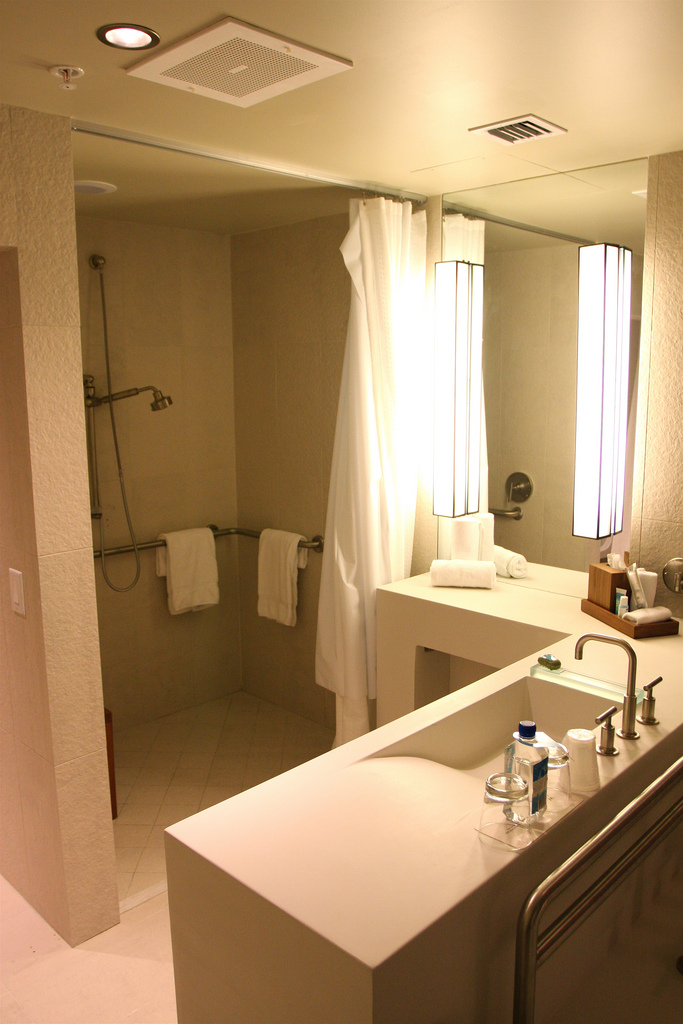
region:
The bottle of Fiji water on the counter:
[502, 711, 556, 831]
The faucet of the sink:
[569, 630, 646, 745]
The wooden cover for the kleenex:
[585, 544, 638, 608]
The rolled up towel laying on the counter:
[419, 550, 510, 595]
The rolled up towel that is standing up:
[446, 507, 477, 577]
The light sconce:
[426, 245, 487, 539]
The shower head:
[79, 242, 178, 619]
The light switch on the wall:
[5, 570, 35, 634]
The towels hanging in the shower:
[143, 514, 318, 629]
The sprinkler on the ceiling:
[32, 50, 92, 100]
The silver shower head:
[151, 388, 177, 416]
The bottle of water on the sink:
[491, 709, 558, 832]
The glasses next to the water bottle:
[477, 739, 573, 848]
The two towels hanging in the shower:
[155, 526, 314, 631]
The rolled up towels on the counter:
[427, 507, 530, 601]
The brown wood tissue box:
[584, 557, 641, 611]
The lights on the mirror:
[430, 241, 640, 540]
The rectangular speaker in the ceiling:
[119, 12, 354, 111]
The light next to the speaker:
[93, 18, 163, 52]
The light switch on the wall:
[3, 564, 31, 622]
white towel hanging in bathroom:
[140, 521, 244, 624]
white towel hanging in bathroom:
[250, 522, 311, 627]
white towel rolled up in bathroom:
[431, 537, 508, 592]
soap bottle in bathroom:
[492, 734, 555, 831]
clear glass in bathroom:
[485, 772, 527, 861]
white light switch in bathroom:
[1, 556, 36, 622]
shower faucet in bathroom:
[112, 380, 198, 414]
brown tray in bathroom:
[580, 563, 663, 631]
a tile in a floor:
[225, 682, 256, 713]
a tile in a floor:
[262, 702, 278, 725]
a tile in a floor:
[276, 705, 316, 736]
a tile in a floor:
[284, 748, 302, 772]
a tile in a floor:
[243, 740, 283, 771]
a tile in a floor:
[216, 730, 248, 756]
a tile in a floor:
[178, 717, 212, 752]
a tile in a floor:
[143, 718, 181, 748]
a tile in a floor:
[158, 778, 196, 804]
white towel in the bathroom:
[156, 524, 228, 614]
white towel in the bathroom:
[247, 524, 300, 627]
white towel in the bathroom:
[420, 549, 484, 586]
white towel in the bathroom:
[486, 539, 524, 578]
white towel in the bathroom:
[449, 503, 475, 564]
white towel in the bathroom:
[469, 502, 492, 565]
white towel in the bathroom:
[619, 596, 666, 623]